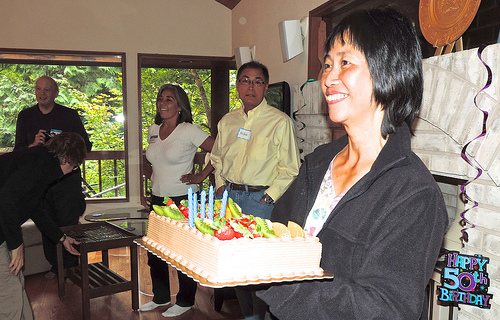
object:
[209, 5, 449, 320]
woman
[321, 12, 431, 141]
hair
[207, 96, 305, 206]
shirt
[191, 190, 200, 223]
candle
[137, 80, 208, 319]
woman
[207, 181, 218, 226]
candle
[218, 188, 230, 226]
candle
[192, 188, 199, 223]
candle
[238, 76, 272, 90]
glasses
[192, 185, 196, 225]
candle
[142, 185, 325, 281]
cake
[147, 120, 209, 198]
shirt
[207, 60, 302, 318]
man